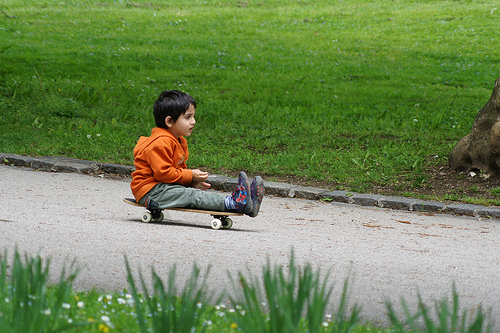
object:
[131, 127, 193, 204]
hoodie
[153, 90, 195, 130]
hair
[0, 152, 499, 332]
path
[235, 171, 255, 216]
sneakers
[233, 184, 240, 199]
shoelaces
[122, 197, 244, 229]
skateboard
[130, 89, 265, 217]
boy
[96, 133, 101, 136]
flowers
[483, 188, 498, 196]
grass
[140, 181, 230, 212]
pants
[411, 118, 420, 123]
flower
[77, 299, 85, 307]
flower